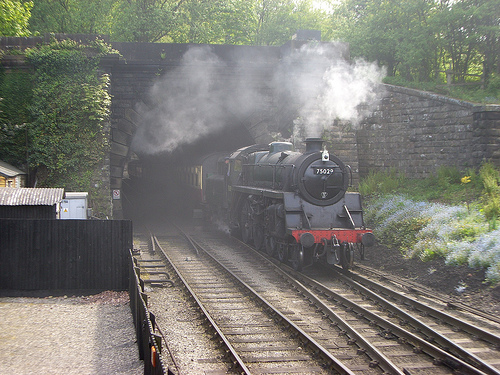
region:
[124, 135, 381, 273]
train on railway tracks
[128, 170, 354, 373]
tracks next to tracks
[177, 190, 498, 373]
tracks next to tracks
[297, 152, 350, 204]
front of black train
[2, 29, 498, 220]
overpath is brick with a tunnel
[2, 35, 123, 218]
ivy on brick wall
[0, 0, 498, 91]
trees on top of overpath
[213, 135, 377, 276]
Black steam engine on tracks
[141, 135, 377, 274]
Antique train emerging from tunnel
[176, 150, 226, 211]
Black and yellow passenger car in tunnel behind engine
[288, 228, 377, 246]
Red "cowcatcher" on front of train engine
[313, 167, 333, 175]
Four digit number on front of train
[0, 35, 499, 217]
Brick wall and arch of tunnel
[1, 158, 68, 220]
Two small tin-roofed buildings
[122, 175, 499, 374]
Multiple train tracks running through tunnel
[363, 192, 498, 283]
Low silvery plants growing on bank beside tracks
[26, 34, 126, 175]
Leafy green vine growing on outside brick wall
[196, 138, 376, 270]
The train is black with red.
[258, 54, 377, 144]
Smoke is coming from the top of the train.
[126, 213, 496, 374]
The tracks are side by side.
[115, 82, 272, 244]
The tunnel is over the tracks.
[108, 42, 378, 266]
The train is passing through the tunnel.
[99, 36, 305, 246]
The tunnel is made of brick.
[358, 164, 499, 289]
Grass and bushes are beside the tracks.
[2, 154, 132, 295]
The small building is beside the tunnel.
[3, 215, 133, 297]
The fence is made of wood.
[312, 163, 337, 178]
A number is on the front of the train.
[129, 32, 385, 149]
steam coming from a stack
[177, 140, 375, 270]
black and red train on tracks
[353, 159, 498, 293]
green and white foilage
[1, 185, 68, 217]
old wood shed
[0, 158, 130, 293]
two sheds behind a wood fence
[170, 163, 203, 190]
windows on a train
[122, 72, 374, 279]
train coming out of a tunnel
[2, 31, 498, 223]
old brick bridge with tunnel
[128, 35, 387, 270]
white smoke coming from a train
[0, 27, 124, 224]
foilage growing on brick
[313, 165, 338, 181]
number on the front of the train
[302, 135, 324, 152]
smoke stack on the train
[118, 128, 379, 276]
train pulling through a tunnel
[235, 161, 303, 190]
rail on the side of a train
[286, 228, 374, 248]
red bumper on a train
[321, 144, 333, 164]
silver bell on a train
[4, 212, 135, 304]
wooden fence by the tracks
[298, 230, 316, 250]
round bumper on the left side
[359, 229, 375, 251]
round bumper on the right side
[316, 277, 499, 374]
track crossover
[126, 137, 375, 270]
A long black and red train with yellow side.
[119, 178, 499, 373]
All of the brown train tracks.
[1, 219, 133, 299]
A small black fence area.